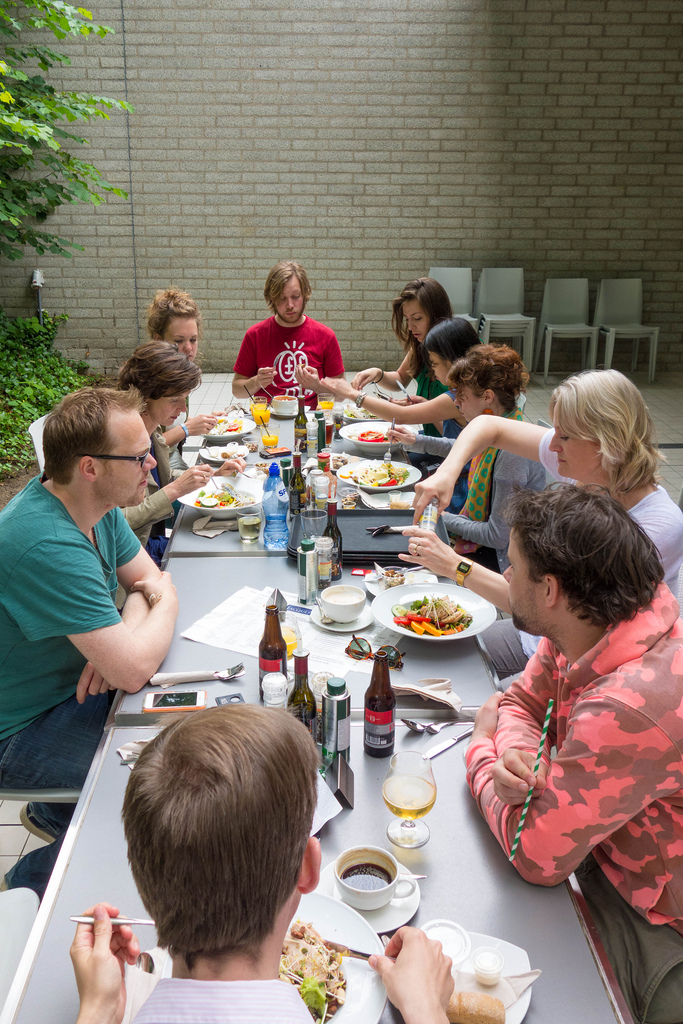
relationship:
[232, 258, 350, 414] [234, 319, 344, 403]
man in shirt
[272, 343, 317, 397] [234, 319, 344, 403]
writing on shirt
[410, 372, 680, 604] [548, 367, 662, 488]
woman has hair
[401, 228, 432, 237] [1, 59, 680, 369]
brick on side of wall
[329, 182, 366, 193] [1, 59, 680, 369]
brick on side of wall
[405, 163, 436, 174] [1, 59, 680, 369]
brick on side of wall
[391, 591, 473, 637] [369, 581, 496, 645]
dish in bowl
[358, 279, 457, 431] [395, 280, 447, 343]
lady has hair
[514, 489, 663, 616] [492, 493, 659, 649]
hair on head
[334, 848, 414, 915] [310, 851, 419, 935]
cup on saucer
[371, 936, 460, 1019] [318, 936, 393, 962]
hand holding knife handle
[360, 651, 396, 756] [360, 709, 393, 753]
bottle has label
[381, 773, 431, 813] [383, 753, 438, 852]
liquid in glass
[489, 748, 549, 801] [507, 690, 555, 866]
hand holding straw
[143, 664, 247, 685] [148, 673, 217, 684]
utensils wrapped in napkin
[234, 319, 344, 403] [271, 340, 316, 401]
shirt has writing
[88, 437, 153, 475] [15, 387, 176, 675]
glasses on man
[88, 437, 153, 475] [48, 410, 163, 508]
glasses on face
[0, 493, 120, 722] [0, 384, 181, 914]
shirt on gentleman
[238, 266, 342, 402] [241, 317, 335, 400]
man wearing shirt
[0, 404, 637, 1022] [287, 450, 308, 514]
table has bottle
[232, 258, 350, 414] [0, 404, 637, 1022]
man at end of table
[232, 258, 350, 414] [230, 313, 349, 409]
man has shirt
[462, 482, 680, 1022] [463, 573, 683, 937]
man has hoodie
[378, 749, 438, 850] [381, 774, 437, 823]
glass has liquid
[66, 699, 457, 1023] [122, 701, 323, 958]
guy has head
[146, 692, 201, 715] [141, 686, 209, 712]
case on phone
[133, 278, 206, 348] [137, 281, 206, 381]
hair on head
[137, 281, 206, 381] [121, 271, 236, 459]
head on lady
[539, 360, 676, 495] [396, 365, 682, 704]
hair on woman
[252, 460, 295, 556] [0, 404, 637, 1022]
bottle on table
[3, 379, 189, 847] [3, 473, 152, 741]
gentleman wearing shirt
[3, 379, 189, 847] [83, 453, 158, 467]
gentleman wearing glasses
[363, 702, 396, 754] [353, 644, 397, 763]
label on bottle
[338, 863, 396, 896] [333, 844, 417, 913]
coffee in cup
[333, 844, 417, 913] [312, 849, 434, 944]
cup on saucer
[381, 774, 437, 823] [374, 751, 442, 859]
liquid in glass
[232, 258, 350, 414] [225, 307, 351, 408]
man wearing shirt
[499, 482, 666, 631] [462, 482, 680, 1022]
hair on man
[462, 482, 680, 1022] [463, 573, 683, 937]
man wearing hoodie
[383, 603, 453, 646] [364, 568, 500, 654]
dish on plate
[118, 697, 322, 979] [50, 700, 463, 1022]
hair on guy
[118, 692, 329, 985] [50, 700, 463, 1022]
hair on guy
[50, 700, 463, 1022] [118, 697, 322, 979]
guy on hair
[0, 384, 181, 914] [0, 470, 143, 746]
gentleman wearing shirt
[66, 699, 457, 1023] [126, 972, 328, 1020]
guy with shirt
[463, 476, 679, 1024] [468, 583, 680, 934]
man with hoodie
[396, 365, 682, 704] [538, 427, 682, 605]
woman wearing t-shirt